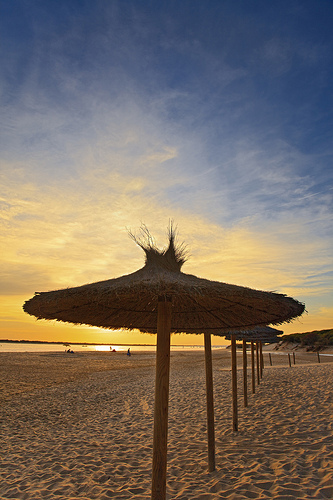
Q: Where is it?
A: This is at the shore.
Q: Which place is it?
A: It is a shore.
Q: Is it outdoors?
A: Yes, it is outdoors.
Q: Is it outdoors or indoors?
A: It is outdoors.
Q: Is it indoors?
A: No, it is outdoors.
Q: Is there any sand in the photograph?
A: Yes, there is sand.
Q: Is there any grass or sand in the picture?
A: Yes, there is sand.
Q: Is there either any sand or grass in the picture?
A: Yes, there is sand.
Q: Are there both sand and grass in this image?
A: Yes, there are both sand and grass.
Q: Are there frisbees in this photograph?
A: No, there are no frisbees.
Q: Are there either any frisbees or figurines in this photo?
A: No, there are no frisbees or figurines.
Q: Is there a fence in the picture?
A: No, there are no fences.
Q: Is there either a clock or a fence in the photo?
A: No, there are no fences or clocks.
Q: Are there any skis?
A: No, there are no skis.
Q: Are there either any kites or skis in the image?
A: No, there are no skis or kites.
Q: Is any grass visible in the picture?
A: Yes, there is grass.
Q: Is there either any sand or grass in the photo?
A: Yes, there is grass.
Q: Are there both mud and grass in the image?
A: No, there is grass but no mud.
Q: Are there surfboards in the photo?
A: No, there are no surfboards.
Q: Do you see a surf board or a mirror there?
A: No, there are no surfboards or mirrors.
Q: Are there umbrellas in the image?
A: Yes, there is an umbrella.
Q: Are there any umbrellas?
A: Yes, there is an umbrella.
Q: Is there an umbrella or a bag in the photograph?
A: Yes, there is an umbrella.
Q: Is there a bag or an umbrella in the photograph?
A: Yes, there is an umbrella.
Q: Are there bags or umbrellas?
A: Yes, there is an umbrella.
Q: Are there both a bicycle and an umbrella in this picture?
A: No, there is an umbrella but no bicycles.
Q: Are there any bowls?
A: No, there are no bowls.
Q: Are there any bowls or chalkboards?
A: No, there are no bowls or chalkboards.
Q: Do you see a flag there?
A: No, there are no flags.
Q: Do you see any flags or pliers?
A: No, there are no flags or pliers.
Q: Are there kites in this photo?
A: No, there are no kites.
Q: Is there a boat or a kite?
A: No, there are no kites or boats.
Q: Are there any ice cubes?
A: No, there are no ice cubes.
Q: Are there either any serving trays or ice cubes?
A: No, there are no ice cubes or serving trays.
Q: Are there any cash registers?
A: No, there are no cash registers.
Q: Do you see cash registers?
A: No, there are no cash registers.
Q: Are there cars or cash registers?
A: No, there are no cash registers or cars.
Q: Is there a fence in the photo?
A: No, there are no fences.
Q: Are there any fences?
A: No, there are no fences.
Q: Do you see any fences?
A: No, there are no fences.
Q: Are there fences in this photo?
A: No, there are no fences.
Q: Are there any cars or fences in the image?
A: No, there are no fences or cars.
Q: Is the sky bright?
A: Yes, the sky is bright.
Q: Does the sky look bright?
A: Yes, the sky is bright.